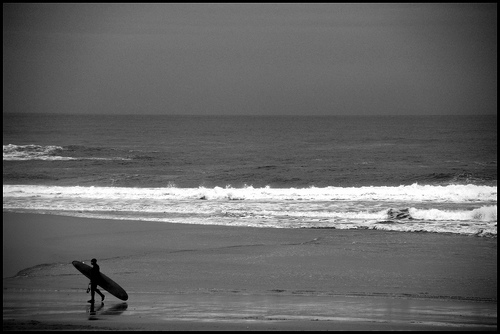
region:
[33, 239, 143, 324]
A man carrying a surfboard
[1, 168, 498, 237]
White capped ocean waves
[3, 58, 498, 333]
A man walking on the beach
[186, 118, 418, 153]
Calm ocean water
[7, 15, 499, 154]
The horizon above the ocean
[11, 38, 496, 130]
The sky above the ocean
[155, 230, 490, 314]
A wet sandy beach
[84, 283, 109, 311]
A man's legs walking on the beach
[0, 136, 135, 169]
An area of waves in the ocean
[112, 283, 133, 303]
The end of a surfboard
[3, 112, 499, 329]
a beach contrasted in black and white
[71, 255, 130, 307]
a surfer walks across the beach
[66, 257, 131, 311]
a surfer waiting for a big wave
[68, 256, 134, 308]
a surfer looking for his next wave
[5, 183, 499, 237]
small waves crash on the beach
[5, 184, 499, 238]
small waves crash and make white foam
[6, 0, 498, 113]
a clear sky without any clouds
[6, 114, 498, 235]
the ocean extends out as far as the eye can see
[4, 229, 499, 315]
a small amount of water makes its way back to the ocean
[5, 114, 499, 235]
a calm ocean without any big waves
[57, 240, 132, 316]
surfer walking on the beach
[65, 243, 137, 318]
surfer holding a surfboard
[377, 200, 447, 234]
wave on the ocean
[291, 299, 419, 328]
sand on the beach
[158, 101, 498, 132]
line on the horizon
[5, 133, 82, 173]
wave on the ocean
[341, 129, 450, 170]
water in the ocean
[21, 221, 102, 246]
sand on the beach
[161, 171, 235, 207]
waves on the ocean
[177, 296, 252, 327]
water on the beach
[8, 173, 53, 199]
Small ripples in the water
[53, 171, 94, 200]
Small ripples in the water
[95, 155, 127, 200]
Small ripples in the water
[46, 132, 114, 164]
Small ripples in the water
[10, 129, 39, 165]
Small ripples in the water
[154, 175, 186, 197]
Small ripples in the water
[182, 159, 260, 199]
Small ripples in the water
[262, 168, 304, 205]
Small ripples in the water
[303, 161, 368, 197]
Small ripples in the water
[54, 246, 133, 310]
surfer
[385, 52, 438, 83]
white clouds in blue sky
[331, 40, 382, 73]
white clouds in blue sky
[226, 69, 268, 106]
white clouds in blue sky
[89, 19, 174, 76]
white clouds in blue sky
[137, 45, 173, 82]
white clouds in blue sky